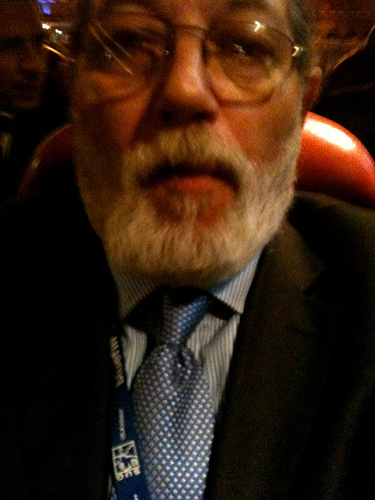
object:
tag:
[111, 437, 142, 481]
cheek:
[69, 63, 158, 229]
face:
[69, 1, 306, 279]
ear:
[304, 65, 325, 109]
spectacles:
[42, 24, 309, 111]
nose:
[153, 21, 221, 121]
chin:
[118, 205, 258, 280]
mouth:
[132, 150, 246, 199]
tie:
[131, 291, 215, 500]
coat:
[0, 178, 375, 500]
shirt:
[106, 254, 266, 496]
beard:
[69, 83, 304, 275]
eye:
[101, 28, 154, 63]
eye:
[217, 32, 277, 66]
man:
[2, 1, 375, 500]